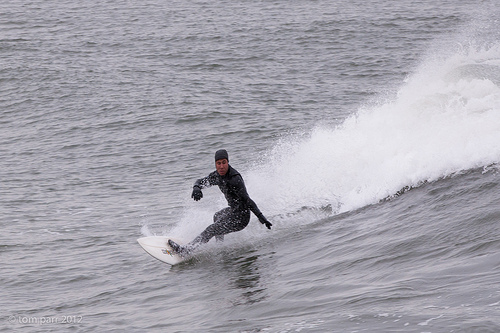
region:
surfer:
[161, 148, 271, 251]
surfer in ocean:
[155, 139, 264, 276]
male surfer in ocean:
[146, 142, 275, 262]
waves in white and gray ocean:
[25, 14, 63, 60]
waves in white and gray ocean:
[271, 151, 316, 218]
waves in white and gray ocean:
[347, 107, 393, 232]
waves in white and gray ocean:
[395, 49, 431, 121]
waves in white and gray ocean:
[442, 113, 473, 183]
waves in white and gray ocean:
[371, 243, 420, 300]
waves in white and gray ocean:
[133, 279, 190, 311]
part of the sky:
[405, 207, 422, 220]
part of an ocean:
[387, 162, 397, 175]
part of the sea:
[389, 217, 406, 225]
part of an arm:
[258, 198, 262, 210]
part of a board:
[144, 238, 166, 280]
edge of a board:
[164, 234, 174, 251]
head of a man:
[221, 153, 222, 168]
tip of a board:
[165, 252, 175, 262]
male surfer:
[140, 135, 288, 252]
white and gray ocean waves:
[11, 13, 61, 67]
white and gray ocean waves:
[66, 86, 114, 138]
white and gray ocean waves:
[330, 128, 375, 159]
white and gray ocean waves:
[343, 162, 421, 256]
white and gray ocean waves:
[390, 53, 434, 107]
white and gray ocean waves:
[407, 162, 492, 216]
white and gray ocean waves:
[283, 125, 334, 157]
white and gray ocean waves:
[24, 220, 102, 257]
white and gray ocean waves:
[266, 249, 334, 284]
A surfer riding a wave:
[133, 142, 280, 268]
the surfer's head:
[211, 148, 233, 176]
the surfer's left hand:
[188, 183, 206, 203]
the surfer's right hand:
[258, 218, 275, 231]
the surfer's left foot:
[166, 237, 188, 255]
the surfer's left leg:
[164, 208, 249, 261]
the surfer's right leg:
[210, 205, 227, 247]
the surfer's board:
[130, 210, 235, 265]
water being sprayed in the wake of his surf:
[176, 18, 496, 263]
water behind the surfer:
[2, 3, 493, 144]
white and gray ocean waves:
[37, 67, 78, 107]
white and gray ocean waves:
[277, 101, 312, 151]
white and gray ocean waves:
[326, 140, 384, 190]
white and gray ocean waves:
[359, 67, 394, 134]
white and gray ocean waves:
[363, 199, 417, 237]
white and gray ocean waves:
[400, 166, 451, 217]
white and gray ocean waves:
[41, 103, 93, 150]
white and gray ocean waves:
[54, 229, 124, 271]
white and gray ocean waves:
[104, 24, 145, 55]